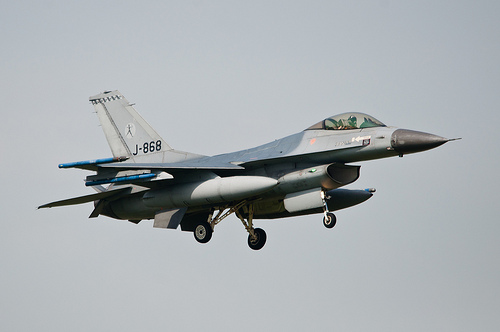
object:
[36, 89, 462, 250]
airplane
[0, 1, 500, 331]
air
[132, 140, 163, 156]
identification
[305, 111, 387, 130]
cockpit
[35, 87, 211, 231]
tail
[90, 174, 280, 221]
missile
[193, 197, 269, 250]
landing gear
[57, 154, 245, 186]
wing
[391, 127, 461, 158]
nose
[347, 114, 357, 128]
pilot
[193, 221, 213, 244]
wheel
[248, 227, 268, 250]
wheel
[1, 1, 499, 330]
sky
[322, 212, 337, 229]
wheel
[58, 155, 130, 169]
weapon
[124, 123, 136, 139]
logo